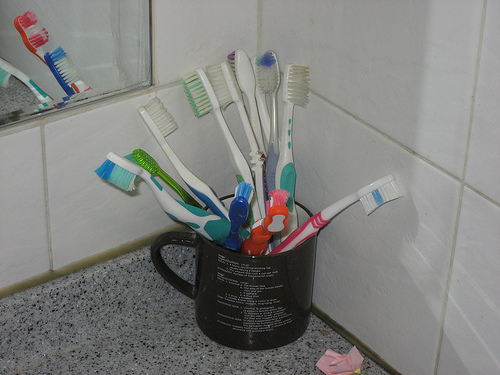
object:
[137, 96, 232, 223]
toothbrush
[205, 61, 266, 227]
toothbrush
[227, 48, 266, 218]
toothbrush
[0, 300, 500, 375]
ground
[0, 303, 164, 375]
granite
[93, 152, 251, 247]
tooth brush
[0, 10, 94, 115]
reflection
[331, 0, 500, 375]
white tile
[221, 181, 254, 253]
blue toothbrush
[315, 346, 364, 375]
paper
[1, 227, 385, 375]
counter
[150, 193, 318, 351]
coffee mug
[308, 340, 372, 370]
wire protector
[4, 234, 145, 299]
grout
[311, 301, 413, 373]
grout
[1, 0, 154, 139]
mirror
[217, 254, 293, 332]
white writing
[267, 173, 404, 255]
toothbrush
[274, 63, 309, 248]
toothbrush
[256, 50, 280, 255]
toothbrush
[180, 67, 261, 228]
toothbrush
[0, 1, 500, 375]
wall